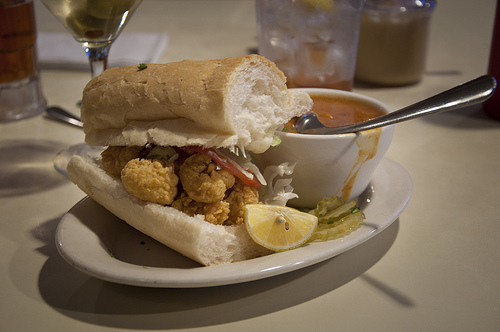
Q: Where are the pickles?
A: On the plate.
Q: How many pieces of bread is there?
A: Two.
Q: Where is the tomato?
A: On the sandwich.